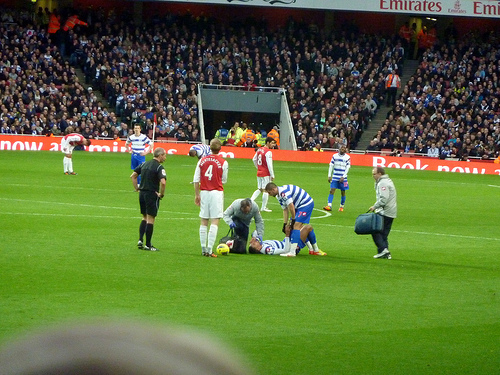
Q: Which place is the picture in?
A: It is at the field.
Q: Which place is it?
A: It is a field.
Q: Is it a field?
A: Yes, it is a field.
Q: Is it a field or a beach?
A: It is a field.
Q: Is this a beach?
A: No, it is a field.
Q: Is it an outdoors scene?
A: Yes, it is outdoors.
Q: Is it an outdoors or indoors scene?
A: It is outdoors.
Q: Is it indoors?
A: No, it is outdoors.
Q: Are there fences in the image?
A: No, there are no fences.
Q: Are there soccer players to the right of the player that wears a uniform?
A: Yes, there is a soccer player to the right of the player.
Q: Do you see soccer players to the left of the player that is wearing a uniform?
A: No, the soccer player is to the right of the player.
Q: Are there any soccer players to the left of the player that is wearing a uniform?
A: No, the soccer player is to the right of the player.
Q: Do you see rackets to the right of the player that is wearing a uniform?
A: No, there is a soccer player to the right of the player.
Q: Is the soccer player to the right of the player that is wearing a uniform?
A: Yes, the soccer player is to the right of the player.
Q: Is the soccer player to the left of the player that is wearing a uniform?
A: No, the soccer player is to the right of the player.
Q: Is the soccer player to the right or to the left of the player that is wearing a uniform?
A: The soccer player is to the right of the player.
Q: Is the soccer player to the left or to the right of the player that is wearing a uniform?
A: The soccer player is to the right of the player.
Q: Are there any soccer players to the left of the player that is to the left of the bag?
A: Yes, there is a soccer player to the left of the player.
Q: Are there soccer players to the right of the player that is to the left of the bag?
A: No, the soccer player is to the left of the player.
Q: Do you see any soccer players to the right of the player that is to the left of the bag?
A: No, the soccer player is to the left of the player.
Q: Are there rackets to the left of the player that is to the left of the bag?
A: No, there is a soccer player to the left of the player.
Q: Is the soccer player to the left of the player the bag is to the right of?
A: Yes, the soccer player is to the left of the player.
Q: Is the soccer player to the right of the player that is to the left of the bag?
A: No, the soccer player is to the left of the player.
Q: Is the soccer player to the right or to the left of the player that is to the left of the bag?
A: The soccer player is to the left of the player.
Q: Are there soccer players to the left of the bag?
A: Yes, there is a soccer player to the left of the bag.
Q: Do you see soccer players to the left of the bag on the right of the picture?
A: Yes, there is a soccer player to the left of the bag.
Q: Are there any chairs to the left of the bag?
A: No, there is a soccer player to the left of the bag.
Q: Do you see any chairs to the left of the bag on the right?
A: No, there is a soccer player to the left of the bag.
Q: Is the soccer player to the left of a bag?
A: Yes, the soccer player is to the left of a bag.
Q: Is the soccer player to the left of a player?
A: Yes, the soccer player is to the left of a player.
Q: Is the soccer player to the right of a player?
A: No, the soccer player is to the left of a player.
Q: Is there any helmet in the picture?
A: No, there are no helmets.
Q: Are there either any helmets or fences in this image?
A: No, there are no helmets or fences.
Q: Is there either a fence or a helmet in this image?
A: No, there are no helmets or fences.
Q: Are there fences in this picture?
A: No, there are no fences.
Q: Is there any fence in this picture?
A: No, there are no fences.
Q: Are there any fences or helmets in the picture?
A: No, there are no fences or helmets.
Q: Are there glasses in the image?
A: No, there are no glasses.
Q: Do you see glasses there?
A: No, there are no glasses.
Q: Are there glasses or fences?
A: No, there are no glasses or fences.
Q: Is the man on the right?
A: Yes, the man is on the right of the image.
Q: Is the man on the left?
A: No, the man is on the right of the image.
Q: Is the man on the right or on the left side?
A: The man is on the right of the image.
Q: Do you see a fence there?
A: No, there are no fences.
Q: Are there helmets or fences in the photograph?
A: No, there are no fences or helmets.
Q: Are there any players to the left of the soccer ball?
A: Yes, there is a player to the left of the soccer ball.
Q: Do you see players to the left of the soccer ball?
A: Yes, there is a player to the left of the soccer ball.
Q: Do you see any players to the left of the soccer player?
A: Yes, there is a player to the left of the soccer player.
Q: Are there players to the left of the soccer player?
A: Yes, there is a player to the left of the soccer player.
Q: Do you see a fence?
A: No, there are no fences.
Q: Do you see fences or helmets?
A: No, there are no fences or helmets.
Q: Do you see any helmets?
A: No, there are no helmets.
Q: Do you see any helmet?
A: No, there are no helmets.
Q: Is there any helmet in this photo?
A: No, there are no helmets.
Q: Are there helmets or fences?
A: No, there are no helmets or fences.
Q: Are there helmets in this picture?
A: No, there are no helmets.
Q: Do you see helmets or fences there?
A: No, there are no helmets or fences.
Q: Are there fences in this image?
A: No, there are no fences.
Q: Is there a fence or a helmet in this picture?
A: No, there are no fences or helmets.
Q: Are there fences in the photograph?
A: No, there are no fences.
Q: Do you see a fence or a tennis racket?
A: No, there are no fences or rackets.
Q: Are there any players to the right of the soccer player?
A: Yes, there is a player to the right of the soccer player.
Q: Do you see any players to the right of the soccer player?
A: Yes, there is a player to the right of the soccer player.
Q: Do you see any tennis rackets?
A: No, there are no tennis rackets.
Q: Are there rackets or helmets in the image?
A: No, there are no rackets or helmets.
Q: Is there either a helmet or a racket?
A: No, there are no rackets or helmets.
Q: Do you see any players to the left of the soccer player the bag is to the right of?
A: Yes, there is a player to the left of the soccer player.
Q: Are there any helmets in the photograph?
A: No, there are no helmets.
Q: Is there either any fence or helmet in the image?
A: No, there are no helmets or fences.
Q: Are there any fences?
A: No, there are no fences.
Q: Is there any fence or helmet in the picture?
A: No, there are no fences or helmets.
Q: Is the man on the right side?
A: Yes, the man is on the right of the image.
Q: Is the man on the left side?
A: No, the man is on the right of the image.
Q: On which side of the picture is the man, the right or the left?
A: The man is on the right of the image.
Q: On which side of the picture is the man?
A: The man is on the right of the image.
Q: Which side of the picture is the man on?
A: The man is on the right of the image.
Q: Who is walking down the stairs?
A: The man is walking down the stairs.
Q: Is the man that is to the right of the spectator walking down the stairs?
A: Yes, the man is walking down the stairs.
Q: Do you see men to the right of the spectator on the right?
A: Yes, there is a man to the right of the spectator.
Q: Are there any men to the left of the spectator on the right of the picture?
A: No, the man is to the right of the spectator.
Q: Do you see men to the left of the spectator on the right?
A: No, the man is to the right of the spectator.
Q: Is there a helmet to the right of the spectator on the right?
A: No, there is a man to the right of the spectator.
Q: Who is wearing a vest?
A: The man is wearing a vest.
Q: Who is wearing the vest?
A: The man is wearing a vest.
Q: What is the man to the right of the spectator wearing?
A: The man is wearing a vest.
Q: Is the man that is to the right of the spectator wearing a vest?
A: Yes, the man is wearing a vest.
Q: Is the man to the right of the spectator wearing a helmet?
A: No, the man is wearing a vest.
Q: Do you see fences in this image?
A: No, there are no fences.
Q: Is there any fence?
A: No, there are no fences.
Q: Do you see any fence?
A: No, there are no fences.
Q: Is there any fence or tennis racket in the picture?
A: No, there are no fences or rackets.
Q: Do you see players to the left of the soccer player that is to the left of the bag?
A: Yes, there is a player to the left of the soccer player.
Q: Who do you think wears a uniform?
A: The player wears a uniform.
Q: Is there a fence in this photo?
A: No, there are no fences.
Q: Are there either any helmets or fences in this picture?
A: No, there are no fences or helmets.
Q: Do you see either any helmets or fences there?
A: No, there are no fences or helmets.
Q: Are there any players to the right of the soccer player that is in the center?
A: Yes, there is a player to the right of the soccer player.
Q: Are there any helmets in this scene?
A: No, there are no helmets.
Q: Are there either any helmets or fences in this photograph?
A: No, there are no helmets or fences.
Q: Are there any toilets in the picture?
A: No, there are no toilets.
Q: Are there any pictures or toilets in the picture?
A: No, there are no toilets or pictures.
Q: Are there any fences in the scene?
A: No, there are no fences.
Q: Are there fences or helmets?
A: No, there are no fences or helmets.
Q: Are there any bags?
A: Yes, there is a bag.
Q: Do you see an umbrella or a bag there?
A: Yes, there is a bag.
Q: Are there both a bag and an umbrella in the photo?
A: No, there is a bag but no umbrellas.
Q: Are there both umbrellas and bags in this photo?
A: No, there is a bag but no umbrellas.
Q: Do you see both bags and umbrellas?
A: No, there is a bag but no umbrellas.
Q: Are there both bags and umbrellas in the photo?
A: No, there is a bag but no umbrellas.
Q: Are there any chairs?
A: No, there are no chairs.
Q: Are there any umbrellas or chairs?
A: No, there are no chairs or umbrellas.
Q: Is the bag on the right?
A: Yes, the bag is on the right of the image.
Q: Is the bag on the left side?
A: No, the bag is on the right of the image.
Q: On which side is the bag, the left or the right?
A: The bag is on the right of the image.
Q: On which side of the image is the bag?
A: The bag is on the right of the image.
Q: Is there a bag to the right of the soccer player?
A: Yes, there is a bag to the right of the soccer player.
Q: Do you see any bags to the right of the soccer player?
A: Yes, there is a bag to the right of the soccer player.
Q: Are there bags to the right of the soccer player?
A: Yes, there is a bag to the right of the soccer player.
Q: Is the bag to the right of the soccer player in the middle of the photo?
A: Yes, the bag is to the right of the soccer player.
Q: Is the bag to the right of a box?
A: No, the bag is to the right of the soccer player.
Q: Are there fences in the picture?
A: No, there are no fences.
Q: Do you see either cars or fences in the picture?
A: No, there are no fences or cars.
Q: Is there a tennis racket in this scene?
A: No, there are no rackets.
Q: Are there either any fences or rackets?
A: No, there are no rackets or fences.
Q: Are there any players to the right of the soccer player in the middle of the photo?
A: Yes, there is a player to the right of the soccer player.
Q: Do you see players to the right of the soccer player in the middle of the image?
A: Yes, there is a player to the right of the soccer player.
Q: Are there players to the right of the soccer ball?
A: Yes, there is a player to the right of the soccer ball.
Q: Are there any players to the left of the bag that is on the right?
A: Yes, there is a player to the left of the bag.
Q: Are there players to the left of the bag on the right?
A: Yes, there is a player to the left of the bag.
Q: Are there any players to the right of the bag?
A: No, the player is to the left of the bag.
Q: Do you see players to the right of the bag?
A: No, the player is to the left of the bag.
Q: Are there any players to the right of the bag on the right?
A: No, the player is to the left of the bag.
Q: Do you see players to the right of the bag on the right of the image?
A: No, the player is to the left of the bag.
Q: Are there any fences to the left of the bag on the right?
A: No, there is a player to the left of the bag.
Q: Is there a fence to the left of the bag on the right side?
A: No, there is a player to the left of the bag.